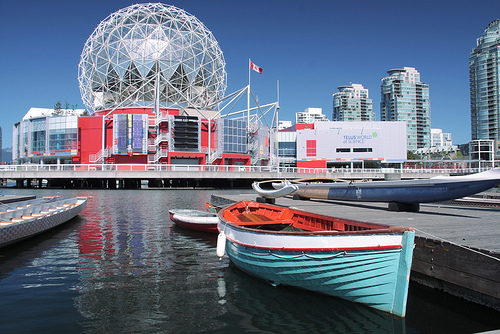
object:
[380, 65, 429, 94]
top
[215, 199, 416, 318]
boat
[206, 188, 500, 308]
dock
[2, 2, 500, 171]
city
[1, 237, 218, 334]
water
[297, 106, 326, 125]
buildings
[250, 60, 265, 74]
flag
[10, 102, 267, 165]
building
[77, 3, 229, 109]
circle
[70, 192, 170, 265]
reflection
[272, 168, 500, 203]
boat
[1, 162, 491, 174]
railing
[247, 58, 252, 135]
pole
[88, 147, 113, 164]
staircase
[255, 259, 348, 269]
stripe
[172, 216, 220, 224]
bumper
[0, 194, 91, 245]
boat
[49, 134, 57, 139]
windows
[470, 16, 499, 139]
building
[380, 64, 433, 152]
building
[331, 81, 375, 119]
building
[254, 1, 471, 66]
sky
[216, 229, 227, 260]
flotation device